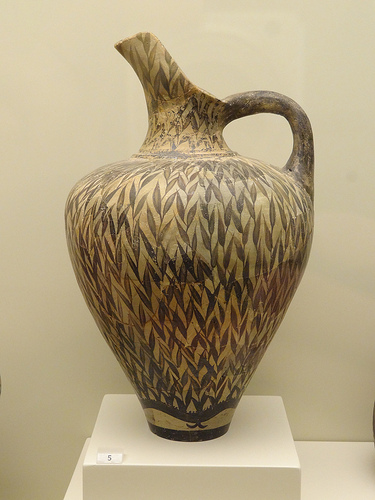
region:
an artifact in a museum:
[64, 31, 314, 498]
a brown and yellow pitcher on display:
[64, 31, 317, 442]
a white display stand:
[81, 393, 301, 497]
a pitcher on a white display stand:
[63, 30, 315, 499]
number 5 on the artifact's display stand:
[95, 451, 121, 466]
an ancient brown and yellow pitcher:
[64, 32, 314, 441]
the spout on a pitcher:
[113, 31, 223, 101]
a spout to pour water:
[114, 31, 220, 100]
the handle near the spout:
[221, 82, 320, 189]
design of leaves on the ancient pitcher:
[95, 180, 288, 293]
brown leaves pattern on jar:
[123, 186, 234, 348]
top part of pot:
[75, 20, 197, 111]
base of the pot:
[146, 400, 241, 473]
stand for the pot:
[169, 445, 254, 487]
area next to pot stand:
[305, 443, 367, 499]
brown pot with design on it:
[126, 189, 261, 309]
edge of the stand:
[267, 442, 314, 494]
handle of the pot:
[238, 67, 331, 152]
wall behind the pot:
[50, 54, 104, 101]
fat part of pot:
[119, 161, 289, 271]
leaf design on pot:
[144, 315, 228, 388]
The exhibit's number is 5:
[100, 452, 128, 465]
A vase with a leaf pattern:
[116, 157, 253, 430]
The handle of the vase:
[215, 88, 321, 193]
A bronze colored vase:
[99, 93, 250, 439]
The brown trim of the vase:
[142, 396, 230, 436]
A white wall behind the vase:
[5, 186, 60, 421]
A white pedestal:
[98, 429, 294, 497]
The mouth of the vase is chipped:
[129, 35, 220, 105]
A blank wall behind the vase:
[11, 271, 88, 408]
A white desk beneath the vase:
[298, 427, 359, 497]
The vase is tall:
[50, 28, 309, 465]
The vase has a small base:
[52, 89, 325, 450]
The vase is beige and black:
[51, 33, 322, 465]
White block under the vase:
[54, 378, 320, 492]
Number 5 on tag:
[90, 443, 132, 471]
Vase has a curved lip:
[106, 16, 217, 122]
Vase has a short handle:
[190, 63, 334, 203]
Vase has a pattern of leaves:
[34, 22, 334, 402]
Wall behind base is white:
[12, 21, 359, 422]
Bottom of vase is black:
[137, 399, 239, 447]